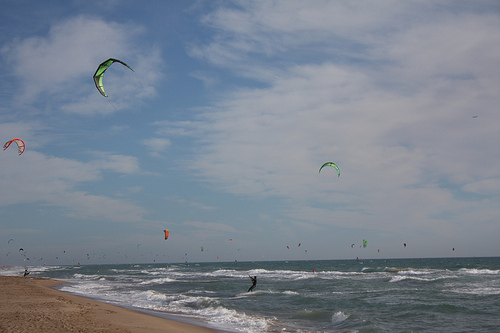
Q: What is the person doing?
A: Kitesurfing.